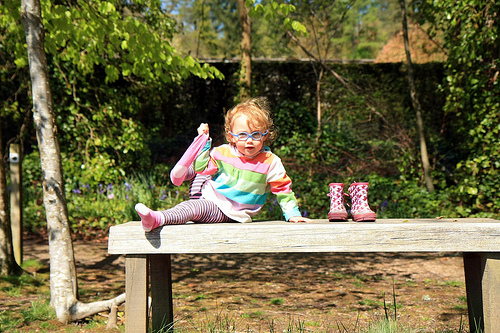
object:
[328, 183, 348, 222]
boot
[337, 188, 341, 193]
spots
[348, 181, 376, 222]
boot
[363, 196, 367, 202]
spots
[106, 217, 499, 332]
bench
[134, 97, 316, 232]
child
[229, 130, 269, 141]
glasses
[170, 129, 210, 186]
sock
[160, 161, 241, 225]
stripes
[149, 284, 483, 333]
grass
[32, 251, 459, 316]
shadows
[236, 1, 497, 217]
trees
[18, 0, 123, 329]
trunk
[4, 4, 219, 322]
tree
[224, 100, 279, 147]
blonde hair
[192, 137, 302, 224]
stripes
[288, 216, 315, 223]
hand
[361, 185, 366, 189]
hearts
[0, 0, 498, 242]
background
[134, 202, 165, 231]
socks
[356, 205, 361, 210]
spots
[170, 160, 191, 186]
right foot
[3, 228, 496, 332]
ground